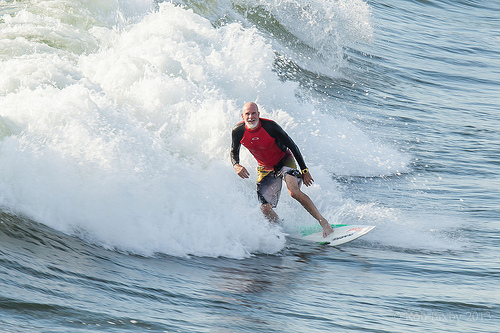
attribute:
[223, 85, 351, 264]
man — wearing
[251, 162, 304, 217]
swimsuit — yellow, black , white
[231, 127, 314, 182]
surfshirt — black , red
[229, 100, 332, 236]
man — old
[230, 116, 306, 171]
shirt — black , red 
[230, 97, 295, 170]
man — surfing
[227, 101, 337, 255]
man — surfing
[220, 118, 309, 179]
rash guard — red, black 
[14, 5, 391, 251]
wave — breaking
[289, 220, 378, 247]
board — blue , white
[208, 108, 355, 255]
man — standing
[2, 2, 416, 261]
wave — crashing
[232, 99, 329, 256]
man — surfing